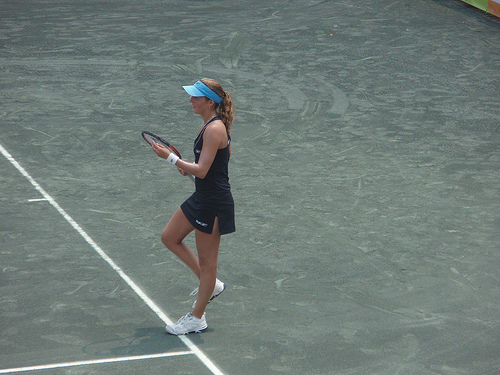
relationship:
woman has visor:
[148, 73, 240, 337] [182, 73, 222, 105]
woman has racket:
[148, 73, 240, 337] [139, 124, 202, 181]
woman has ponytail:
[148, 73, 240, 337] [217, 91, 239, 120]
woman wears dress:
[148, 73, 240, 337] [181, 117, 239, 236]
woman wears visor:
[148, 73, 240, 337] [182, 73, 222, 105]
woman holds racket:
[148, 73, 240, 337] [139, 124, 202, 181]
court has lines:
[2, 2, 498, 374] [1, 146, 223, 372]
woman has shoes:
[148, 73, 240, 337] [165, 280, 229, 335]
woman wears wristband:
[148, 73, 240, 337] [166, 148, 183, 168]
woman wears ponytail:
[148, 73, 240, 337] [217, 91, 239, 120]